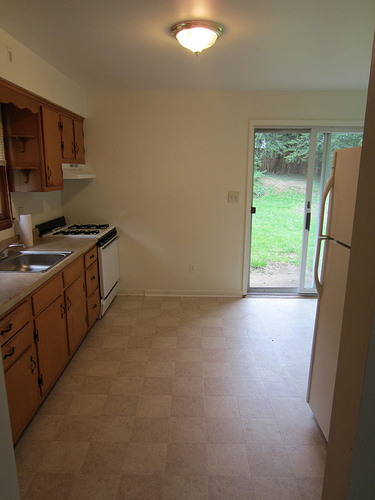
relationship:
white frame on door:
[242, 118, 255, 289] [253, 125, 319, 293]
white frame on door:
[247, 116, 365, 132] [253, 125, 319, 293]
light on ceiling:
[171, 19, 223, 57] [4, 0, 362, 94]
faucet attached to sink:
[2, 238, 29, 257] [1, 240, 79, 285]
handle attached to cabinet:
[59, 303, 67, 317] [29, 289, 104, 380]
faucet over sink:
[2, 243, 27, 257] [0, 242, 75, 275]